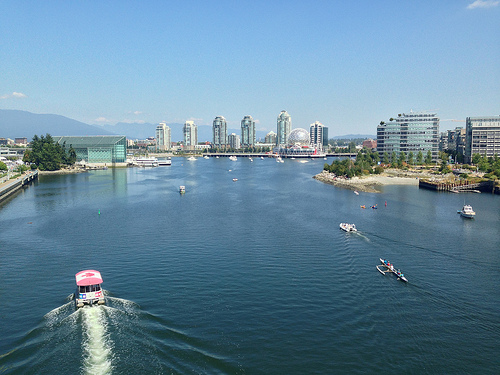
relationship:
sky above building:
[0, 2, 499, 141] [276, 109, 293, 150]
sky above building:
[0, 2, 499, 141] [239, 113, 257, 148]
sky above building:
[0, 2, 499, 141] [211, 114, 230, 148]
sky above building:
[0, 2, 499, 141] [181, 119, 198, 147]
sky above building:
[0, 2, 499, 141] [154, 121, 172, 153]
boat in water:
[73, 267, 107, 312] [0, 158, 499, 373]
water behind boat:
[45, 297, 140, 374] [73, 267, 107, 312]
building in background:
[309, 120, 330, 152] [0, 105, 497, 166]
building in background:
[239, 113, 257, 148] [0, 105, 497, 166]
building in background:
[276, 109, 293, 150] [0, 105, 497, 166]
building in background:
[181, 119, 198, 147] [0, 105, 497, 166]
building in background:
[11, 134, 27, 151] [0, 105, 497, 166]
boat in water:
[338, 220, 362, 234] [0, 158, 499, 373]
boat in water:
[459, 197, 477, 219] [0, 158, 499, 373]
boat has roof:
[73, 267, 107, 312] [76, 266, 103, 288]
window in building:
[409, 130, 416, 135] [372, 111, 442, 169]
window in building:
[385, 130, 393, 134] [372, 111, 442, 169]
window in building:
[418, 131, 424, 136] [372, 111, 442, 169]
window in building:
[400, 148, 408, 152] [372, 111, 442, 169]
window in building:
[423, 140, 431, 145] [372, 111, 442, 169]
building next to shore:
[372, 111, 442, 169] [312, 161, 499, 193]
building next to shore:
[462, 116, 497, 168] [312, 161, 499, 193]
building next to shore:
[446, 127, 467, 160] [312, 161, 499, 193]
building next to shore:
[440, 130, 450, 156] [312, 161, 499, 193]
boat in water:
[175, 183, 188, 199] [0, 158, 499, 373]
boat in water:
[185, 156, 198, 165] [0, 158, 499, 373]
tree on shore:
[424, 148, 434, 168] [312, 161, 499, 193]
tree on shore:
[416, 149, 426, 168] [312, 161, 499, 193]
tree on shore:
[406, 151, 415, 170] [312, 161, 499, 193]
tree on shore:
[399, 150, 407, 171] [312, 161, 499, 193]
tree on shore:
[387, 150, 397, 168] [312, 161, 499, 193]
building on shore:
[287, 127, 311, 149] [144, 148, 358, 160]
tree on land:
[67, 142, 80, 169] [31, 163, 102, 174]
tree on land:
[59, 140, 69, 166] [31, 163, 102, 174]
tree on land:
[38, 141, 61, 171] [31, 163, 102, 174]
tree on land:
[31, 133, 43, 164] [31, 163, 102, 174]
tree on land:
[22, 146, 33, 169] [31, 163, 102, 174]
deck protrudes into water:
[418, 178, 487, 190] [0, 158, 499, 373]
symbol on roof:
[78, 272, 97, 280] [76, 266, 103, 288]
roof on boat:
[76, 266, 103, 288] [73, 267, 107, 312]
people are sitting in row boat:
[381, 258, 405, 279] [375, 255, 409, 287]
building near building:
[287, 127, 311, 149] [309, 120, 330, 152]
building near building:
[287, 127, 311, 149] [276, 109, 293, 150]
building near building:
[287, 127, 311, 149] [239, 113, 257, 148]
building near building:
[287, 127, 311, 149] [211, 114, 230, 148]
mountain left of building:
[1, 108, 118, 138] [154, 121, 172, 153]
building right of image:
[372, 111, 442, 169] [3, 4, 498, 374]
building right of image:
[462, 116, 497, 168] [3, 4, 498, 374]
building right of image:
[446, 127, 467, 160] [3, 4, 498, 374]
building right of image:
[440, 130, 450, 156] [3, 4, 498, 374]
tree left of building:
[67, 142, 80, 169] [154, 121, 172, 153]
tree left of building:
[59, 140, 69, 166] [154, 121, 172, 153]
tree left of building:
[38, 141, 61, 171] [154, 121, 172, 153]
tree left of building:
[31, 133, 43, 164] [154, 121, 172, 153]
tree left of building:
[22, 146, 33, 169] [154, 121, 172, 153]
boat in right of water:
[459, 197, 477, 219] [0, 158, 499, 373]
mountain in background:
[1, 108, 118, 138] [0, 105, 497, 166]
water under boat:
[0, 158, 499, 373] [73, 267, 107, 312]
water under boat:
[0, 158, 499, 373] [175, 183, 188, 199]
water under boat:
[0, 158, 499, 373] [185, 156, 198, 165]